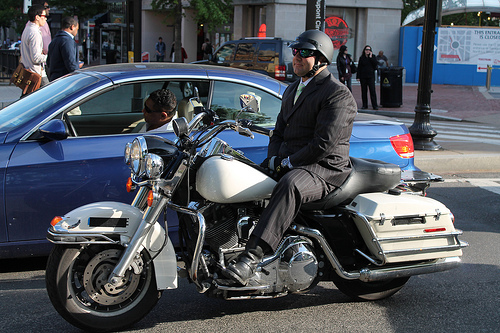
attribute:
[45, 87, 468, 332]
motorcycle — white, silver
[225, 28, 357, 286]
man — person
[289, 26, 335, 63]
helmet — black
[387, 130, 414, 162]
brake light — red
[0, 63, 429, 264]
car — blue, two door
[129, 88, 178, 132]
man — person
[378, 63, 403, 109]
recycling bin — recycling bin, black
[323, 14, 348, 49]
neon sign — red, round, black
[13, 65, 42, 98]
satchel — brown, leather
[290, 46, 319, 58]
sunglasses — black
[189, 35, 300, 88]
suv — parked, black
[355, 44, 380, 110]
woman — person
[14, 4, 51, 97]
man — person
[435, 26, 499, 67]
map — white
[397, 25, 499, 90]
wall — blue